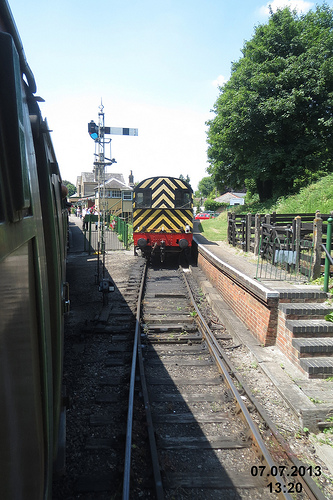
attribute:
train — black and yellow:
[131, 175, 191, 266]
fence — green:
[82, 212, 124, 247]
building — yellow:
[92, 176, 134, 232]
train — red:
[132, 226, 203, 247]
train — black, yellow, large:
[127, 175, 195, 257]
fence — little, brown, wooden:
[226, 206, 331, 276]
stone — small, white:
[239, 394, 248, 402]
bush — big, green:
[176, 11, 330, 199]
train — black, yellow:
[131, 175, 199, 261]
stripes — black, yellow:
[146, 209, 187, 224]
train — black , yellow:
[130, 176, 191, 256]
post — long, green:
[323, 218, 331, 293]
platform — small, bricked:
[199, 234, 320, 302]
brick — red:
[245, 309, 257, 333]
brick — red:
[266, 318, 278, 338]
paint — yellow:
[33, 245, 45, 289]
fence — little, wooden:
[224, 209, 322, 279]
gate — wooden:
[226, 208, 321, 279]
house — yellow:
[93, 175, 132, 213]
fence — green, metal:
[81, 213, 126, 252]